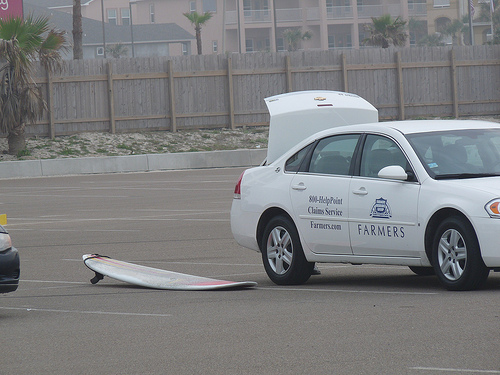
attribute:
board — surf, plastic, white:
[63, 189, 310, 323]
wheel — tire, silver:
[222, 204, 343, 296]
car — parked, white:
[200, 55, 486, 307]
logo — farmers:
[345, 184, 421, 259]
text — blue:
[354, 224, 422, 249]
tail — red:
[225, 165, 257, 199]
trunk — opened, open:
[213, 72, 401, 219]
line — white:
[52, 301, 118, 327]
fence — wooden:
[12, 36, 281, 167]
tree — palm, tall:
[0, 16, 74, 150]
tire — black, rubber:
[402, 202, 485, 314]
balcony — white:
[228, 12, 308, 40]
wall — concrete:
[102, 37, 177, 73]